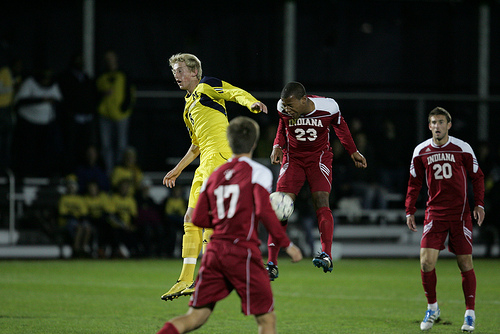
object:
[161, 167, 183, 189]
hand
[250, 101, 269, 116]
hand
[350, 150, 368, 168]
hand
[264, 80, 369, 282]
man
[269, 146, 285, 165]
hand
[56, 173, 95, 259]
person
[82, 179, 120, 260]
person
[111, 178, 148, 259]
child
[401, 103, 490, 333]
man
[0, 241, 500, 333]
field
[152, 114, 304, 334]
man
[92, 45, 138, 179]
spectators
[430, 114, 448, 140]
face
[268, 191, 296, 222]
soccer ball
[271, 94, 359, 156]
shirt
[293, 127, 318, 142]
number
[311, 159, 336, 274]
leg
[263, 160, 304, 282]
leg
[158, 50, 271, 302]
men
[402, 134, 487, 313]
uniforms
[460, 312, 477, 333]
shoes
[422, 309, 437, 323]
laces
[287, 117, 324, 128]
indiana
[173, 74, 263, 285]
uniform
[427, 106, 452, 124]
hair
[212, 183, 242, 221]
number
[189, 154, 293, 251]
shirt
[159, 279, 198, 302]
shoes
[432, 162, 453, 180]
number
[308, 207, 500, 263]
benches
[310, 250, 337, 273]
shoes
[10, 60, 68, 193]
spectator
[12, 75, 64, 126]
shirt